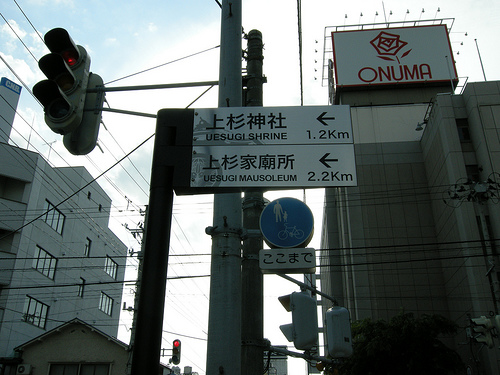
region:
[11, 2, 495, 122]
clouds in blue sky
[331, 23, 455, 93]
red and white sign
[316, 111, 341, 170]
two arrows on signs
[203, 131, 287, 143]
black words on white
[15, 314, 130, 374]
front of slanted roof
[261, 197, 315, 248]
blue and white sign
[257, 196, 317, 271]
round sign over rectangle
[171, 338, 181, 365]
glowing red traffic light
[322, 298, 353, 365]
back of traffic light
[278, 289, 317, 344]
side of traffic light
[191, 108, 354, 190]
white and black street sign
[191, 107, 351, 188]
street sign on post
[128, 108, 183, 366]
black iron sign post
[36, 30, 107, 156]
black electronic stop light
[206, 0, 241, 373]
grey metal lamp post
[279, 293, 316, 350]
white electronic walking sign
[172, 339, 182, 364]
stop light on post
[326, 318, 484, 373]
tree with green leaves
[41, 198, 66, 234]
glass window on building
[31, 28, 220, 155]
the traffic lights hanging above the street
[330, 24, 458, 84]
the sign on the building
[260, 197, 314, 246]
the blue circle sign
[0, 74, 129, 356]
the large building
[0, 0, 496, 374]
the power lines high in the air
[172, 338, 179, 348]
the red traffic light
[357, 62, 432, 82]
the word ONUMA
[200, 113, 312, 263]
the foreign letters on the signs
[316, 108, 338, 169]
the black arrows on the signs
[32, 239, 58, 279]
the window on the building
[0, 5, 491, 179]
white clouds in sky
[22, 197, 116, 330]
windows on side of building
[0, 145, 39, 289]
balconies on side of building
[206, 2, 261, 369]
metal and wood pole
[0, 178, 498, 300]
wires suspended in the air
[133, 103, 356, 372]
two signs on pole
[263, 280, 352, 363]
two traffic lights on poles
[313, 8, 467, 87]
lights around rectangle sign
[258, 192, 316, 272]
two different shaped signs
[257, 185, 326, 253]
A round blue sign on the pole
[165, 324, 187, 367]
A traffic light on red.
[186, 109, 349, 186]
Two signs in Japenese.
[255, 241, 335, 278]
A white sign under the blue sign.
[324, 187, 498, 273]
Wires on the poles.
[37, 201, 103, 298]
Windows on the building.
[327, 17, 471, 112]
Red and white sign on top of building.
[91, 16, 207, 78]
The sky is clear and blue.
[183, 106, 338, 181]
The sign is black and white.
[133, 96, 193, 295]
A pole with signs on it.